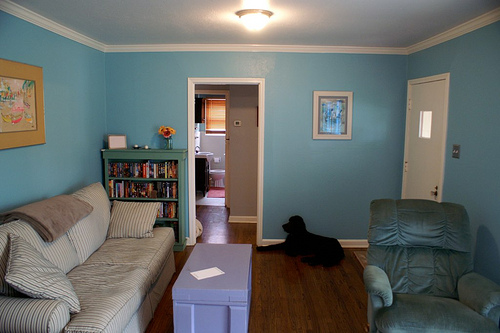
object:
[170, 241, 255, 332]
table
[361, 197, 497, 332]
chair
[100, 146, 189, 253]
bookcase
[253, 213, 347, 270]
dog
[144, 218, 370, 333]
floor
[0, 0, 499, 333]
living room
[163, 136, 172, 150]
vase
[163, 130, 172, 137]
flowers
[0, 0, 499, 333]
room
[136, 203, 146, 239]
stripes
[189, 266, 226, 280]
paper sheet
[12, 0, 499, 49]
ceiling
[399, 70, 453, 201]
door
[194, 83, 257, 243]
doorway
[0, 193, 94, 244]
blanket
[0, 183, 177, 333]
couch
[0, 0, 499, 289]
wall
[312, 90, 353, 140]
wall hanging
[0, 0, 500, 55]
white molding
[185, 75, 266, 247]
door frame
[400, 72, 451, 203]
door frame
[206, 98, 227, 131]
outside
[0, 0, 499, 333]
house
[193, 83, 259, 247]
door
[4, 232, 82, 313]
pillow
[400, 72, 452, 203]
closed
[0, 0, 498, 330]
photo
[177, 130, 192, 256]
part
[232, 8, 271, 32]
light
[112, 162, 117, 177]
book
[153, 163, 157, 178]
book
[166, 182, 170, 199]
book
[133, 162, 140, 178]
book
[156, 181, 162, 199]
book